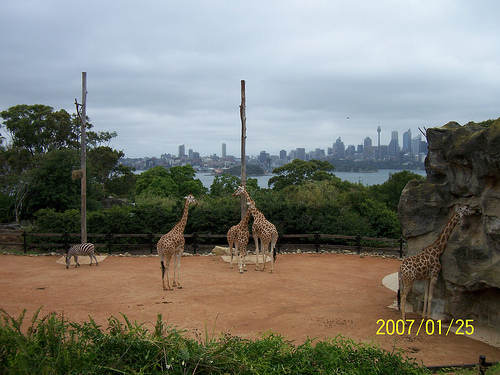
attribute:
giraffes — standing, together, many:
[167, 191, 281, 265]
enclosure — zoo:
[11, 217, 494, 373]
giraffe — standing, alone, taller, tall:
[380, 194, 499, 325]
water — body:
[201, 167, 414, 189]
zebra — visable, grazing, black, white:
[62, 235, 100, 271]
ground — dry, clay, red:
[9, 256, 453, 348]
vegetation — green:
[8, 319, 389, 374]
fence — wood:
[11, 228, 394, 257]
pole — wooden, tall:
[237, 80, 255, 250]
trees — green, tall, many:
[24, 153, 424, 243]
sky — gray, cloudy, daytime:
[4, 8, 496, 140]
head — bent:
[59, 259, 72, 270]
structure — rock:
[382, 126, 494, 306]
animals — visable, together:
[58, 197, 457, 318]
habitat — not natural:
[7, 8, 494, 372]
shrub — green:
[291, 185, 349, 243]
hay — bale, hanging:
[69, 167, 89, 186]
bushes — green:
[111, 176, 396, 232]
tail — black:
[392, 288, 403, 310]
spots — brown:
[407, 250, 433, 274]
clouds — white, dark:
[28, 10, 461, 82]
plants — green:
[6, 162, 400, 231]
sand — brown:
[8, 260, 362, 326]